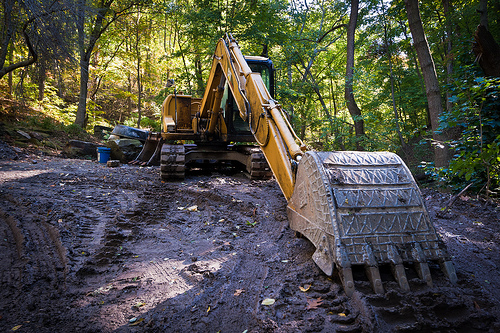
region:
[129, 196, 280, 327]
the ground is muddy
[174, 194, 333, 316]
the ground is muddy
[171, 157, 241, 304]
the ground is muddy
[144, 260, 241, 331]
the ground is muddy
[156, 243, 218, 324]
the ground is muddy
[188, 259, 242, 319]
the ground is muddy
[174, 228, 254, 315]
the ground is muddy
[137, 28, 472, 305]
yellow bulldozer on the dirt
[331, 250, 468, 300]
prongs of the buldizber stciking the mud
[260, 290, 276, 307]
leaf on the mud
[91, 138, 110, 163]
blue container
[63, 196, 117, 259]
tracks in the mud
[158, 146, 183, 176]
mud on the wheel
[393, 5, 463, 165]
skinny tree trunk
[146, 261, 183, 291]
light shining on the dirt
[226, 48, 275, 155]
wire running down the arm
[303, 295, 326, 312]
brown leaf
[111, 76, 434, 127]
the trees are visible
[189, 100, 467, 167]
the trees are visible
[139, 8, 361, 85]
the trees are visible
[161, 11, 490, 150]
the trees are visible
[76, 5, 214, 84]
the trees are visible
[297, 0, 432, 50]
the trees are visible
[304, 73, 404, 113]
the trees are visible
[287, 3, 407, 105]
the trees are visible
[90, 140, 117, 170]
blue buck on the ground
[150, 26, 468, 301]
a parked yellow backhoe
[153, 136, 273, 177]
metal tracks the backhoe moves on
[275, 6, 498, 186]
green trees in the background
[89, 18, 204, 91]
sun shining through the trees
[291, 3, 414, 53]
blue sky showing through the trees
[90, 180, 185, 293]
backhoe tracks in the mud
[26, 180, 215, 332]
muddy ground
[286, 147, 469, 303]
silver dirty backhoe bucket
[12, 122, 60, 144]
rocks laying in the grass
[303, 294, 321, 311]
fall colored leaf on ground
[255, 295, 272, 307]
fall colored leaf on ground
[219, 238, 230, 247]
fall colored leaf on ground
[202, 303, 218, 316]
fall colored leaf on ground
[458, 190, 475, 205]
fall colored leaf on ground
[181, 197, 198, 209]
fall colored leaf on ground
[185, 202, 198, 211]
fall colored leaf on ground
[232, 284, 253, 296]
fall colored leaf on ground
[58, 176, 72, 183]
fall colored leaf on ground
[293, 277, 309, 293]
fall colored leaf on ground